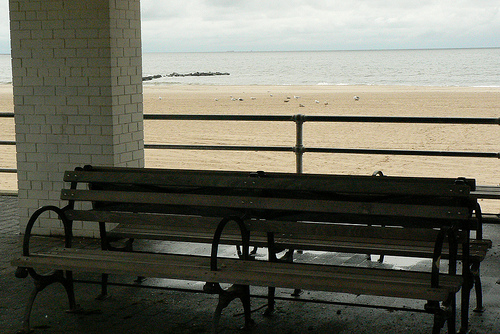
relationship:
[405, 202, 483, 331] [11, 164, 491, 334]
arm on bench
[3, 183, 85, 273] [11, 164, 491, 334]
arm on bench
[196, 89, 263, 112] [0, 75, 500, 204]
birds on sand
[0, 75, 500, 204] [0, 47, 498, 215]
sand on beach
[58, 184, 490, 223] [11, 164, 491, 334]
slate on bench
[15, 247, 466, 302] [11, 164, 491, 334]
planks on bench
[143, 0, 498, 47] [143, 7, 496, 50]
cloud in sky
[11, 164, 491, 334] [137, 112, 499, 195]
bench facing railing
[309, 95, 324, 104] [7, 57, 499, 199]
bird on beach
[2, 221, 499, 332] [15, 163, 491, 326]
brick floor under benches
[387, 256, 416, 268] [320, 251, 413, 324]
water on brick floor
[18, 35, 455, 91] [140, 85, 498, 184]
water past sand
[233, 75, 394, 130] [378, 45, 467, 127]
seagulls on beach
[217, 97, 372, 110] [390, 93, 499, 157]
seagulls on beach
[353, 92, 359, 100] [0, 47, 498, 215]
seagull on beach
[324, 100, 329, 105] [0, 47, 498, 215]
seagull on beach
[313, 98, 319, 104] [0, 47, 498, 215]
seagull on beach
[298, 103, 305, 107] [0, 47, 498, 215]
seagull on beach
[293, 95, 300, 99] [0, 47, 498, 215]
seagull on beach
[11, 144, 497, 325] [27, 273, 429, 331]
bench on concrete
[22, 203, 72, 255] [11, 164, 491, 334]
metal bars on bench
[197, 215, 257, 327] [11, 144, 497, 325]
bar on bench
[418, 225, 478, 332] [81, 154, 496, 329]
bar on bench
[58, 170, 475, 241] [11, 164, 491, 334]
wooden slats on bench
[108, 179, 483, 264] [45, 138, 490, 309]
slate on bench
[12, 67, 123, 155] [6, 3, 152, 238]
support made bricks